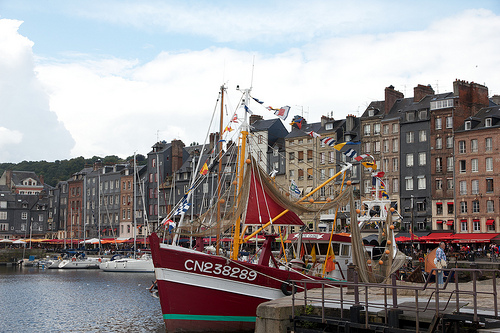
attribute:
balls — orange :
[386, 206, 395, 261]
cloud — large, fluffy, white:
[6, 16, 60, 110]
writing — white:
[185, 259, 257, 282]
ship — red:
[143, 137, 376, 331]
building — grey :
[396, 90, 429, 232]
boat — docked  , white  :
[55, 251, 103, 273]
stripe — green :
[158, 306, 252, 331]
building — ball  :
[378, 95, 473, 218]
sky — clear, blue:
[0, 0, 497, 78]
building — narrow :
[396, 103, 497, 224]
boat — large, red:
[137, 84, 371, 329]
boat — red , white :
[134, 67, 451, 331]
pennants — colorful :
[256, 97, 403, 189]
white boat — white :
[100, 148, 158, 273]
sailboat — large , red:
[146, 83, 366, 331]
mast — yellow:
[153, 95, 431, 298]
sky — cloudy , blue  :
[1, 1, 497, 166]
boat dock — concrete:
[278, 257, 461, 315]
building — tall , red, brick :
[432, 72, 474, 216]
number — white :
[246, 269, 256, 282]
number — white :
[239, 268, 247, 279]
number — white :
[230, 265, 239, 276]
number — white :
[222, 265, 229, 275]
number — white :
[212, 260, 221, 274]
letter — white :
[192, 258, 204, 273]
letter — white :
[182, 256, 194, 271]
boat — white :
[148, 84, 385, 331]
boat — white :
[99, 152, 163, 274]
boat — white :
[56, 172, 120, 269]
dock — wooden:
[313, 280, 451, 329]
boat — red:
[177, 120, 355, 330]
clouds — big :
[5, 19, 453, 93]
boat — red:
[137, 189, 278, 315]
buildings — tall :
[7, 121, 484, 218]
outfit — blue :
[434, 252, 445, 276]